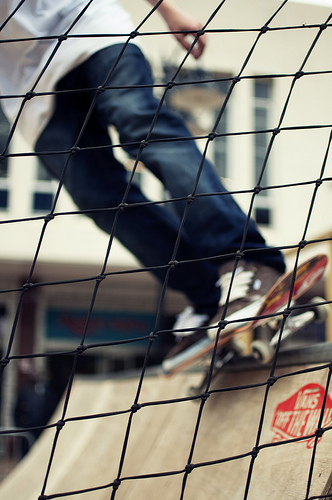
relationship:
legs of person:
[63, 113, 228, 254] [0, 4, 284, 363]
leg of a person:
[89, 42, 265, 269] [0, 4, 284, 363]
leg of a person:
[89, 42, 283, 274] [0, 4, 284, 363]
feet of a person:
[133, 197, 313, 356] [0, 4, 284, 363]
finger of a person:
[168, 16, 211, 62] [0, 4, 284, 363]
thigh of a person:
[110, 46, 134, 145] [0, 4, 284, 363]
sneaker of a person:
[206, 260, 283, 336] [0, 4, 284, 363]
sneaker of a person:
[160, 306, 224, 370] [0, 4, 284, 363]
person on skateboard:
[0, 4, 284, 363] [146, 219, 306, 428]